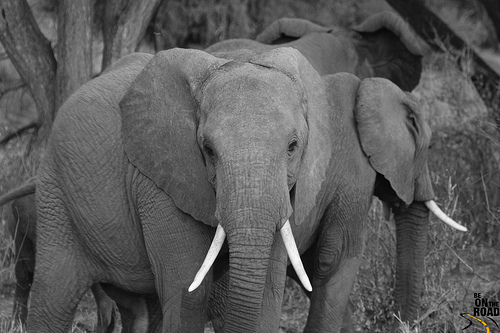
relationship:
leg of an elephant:
[24, 182, 93, 332] [23, 50, 325, 331]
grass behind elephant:
[440, 121, 492, 302] [34, 50, 464, 330]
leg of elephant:
[300, 174, 379, 332] [306, 68, 468, 324]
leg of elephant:
[136, 195, 216, 330] [23, 50, 325, 331]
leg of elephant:
[24, 182, 93, 332] [100, 69, 471, 331]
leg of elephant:
[101, 283, 149, 332] [129, 9, 428, 269]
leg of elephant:
[237, 212, 301, 332] [23, 50, 325, 331]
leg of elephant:
[300, 202, 374, 332] [100, 69, 471, 331]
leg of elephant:
[15, 182, 117, 329] [30, 28, 384, 304]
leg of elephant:
[92, 288, 141, 331] [23, 50, 325, 331]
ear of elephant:
[119, 48, 229, 228] [36, 43, 388, 328]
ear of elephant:
[119, 48, 229, 228] [34, 73, 324, 331]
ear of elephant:
[353, 72, 420, 208] [306, 68, 468, 324]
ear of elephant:
[118, 41, 219, 228] [23, 50, 325, 331]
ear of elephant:
[258, 37, 334, 223] [306, 68, 468, 324]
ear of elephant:
[353, 72, 420, 208] [251, 5, 426, 107]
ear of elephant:
[351, 10, 426, 104] [306, 68, 468, 324]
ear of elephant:
[255, 10, 332, 50] [251, 5, 426, 107]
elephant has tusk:
[23, 50, 325, 331] [426, 198, 467, 232]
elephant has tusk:
[23, 50, 325, 331] [377, 199, 388, 221]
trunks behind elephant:
[3, 0, 158, 63] [23, 50, 325, 331]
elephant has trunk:
[23, 50, 325, 331] [214, 202, 276, 331]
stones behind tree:
[13, 197, 33, 299] [0, 0, 160, 147]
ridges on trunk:
[233, 232, 258, 316] [221, 212, 273, 332]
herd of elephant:
[19, 10, 469, 331] [205, 11, 427, 92]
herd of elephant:
[19, 10, 469, 331] [306, 68, 468, 324]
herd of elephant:
[19, 10, 469, 331] [23, 50, 325, 331]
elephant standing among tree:
[23, 50, 325, 331] [0, 0, 160, 147]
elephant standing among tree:
[306, 68, 468, 324] [0, 0, 160, 147]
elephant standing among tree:
[254, 10, 429, 90] [0, 0, 160, 147]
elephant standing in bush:
[203, 10, 423, 94] [441, 134, 495, 330]